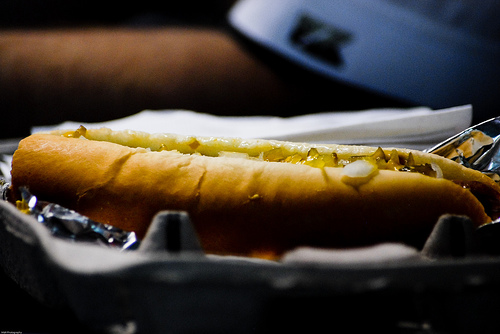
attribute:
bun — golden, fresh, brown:
[71, 154, 178, 208]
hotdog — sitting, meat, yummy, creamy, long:
[54, 112, 472, 220]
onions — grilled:
[346, 168, 378, 187]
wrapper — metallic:
[50, 207, 94, 236]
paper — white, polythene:
[398, 102, 435, 144]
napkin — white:
[318, 115, 416, 141]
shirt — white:
[262, 4, 463, 79]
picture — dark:
[5, 0, 499, 311]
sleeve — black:
[365, 7, 481, 109]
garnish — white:
[290, 140, 415, 186]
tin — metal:
[67, 243, 402, 325]